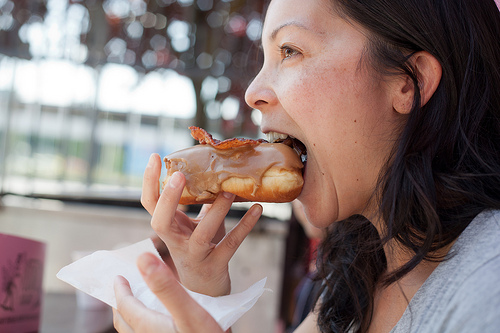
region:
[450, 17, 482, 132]
a person with black hair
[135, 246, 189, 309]
the thumb of a person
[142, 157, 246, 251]
the fingers of a person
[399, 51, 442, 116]
the left ear of a person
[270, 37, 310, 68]
the left eye of a person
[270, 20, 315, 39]
a person's eyebrow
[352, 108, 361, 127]
a mole on a person's skin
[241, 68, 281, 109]
a person's nose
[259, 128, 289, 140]
a person's teeth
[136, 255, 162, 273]
a person's fingernail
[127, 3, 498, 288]
The woman is holding a donut.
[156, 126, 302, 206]
The donut is brown.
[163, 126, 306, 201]
The donut has back on top.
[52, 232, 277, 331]
The woman is holding a napkin.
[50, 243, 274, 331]
The napkin is white in color.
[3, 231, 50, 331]
The object in the background is red and black.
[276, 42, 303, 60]
The woman's eye is brown.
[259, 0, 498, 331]
The woman's hair is brown.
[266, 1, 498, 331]
The woman's hair is long.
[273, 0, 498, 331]
The woman's shirt is gray.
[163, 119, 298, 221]
doughnut in woman's mouth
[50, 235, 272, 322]
napkin in woman's hand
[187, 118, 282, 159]
chip on a doughnut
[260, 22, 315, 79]
left eye on a woman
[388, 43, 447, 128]
left ear of a woman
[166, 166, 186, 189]
nail on a finger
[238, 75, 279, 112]
nose on a woman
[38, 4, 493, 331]
woman eating a doughnut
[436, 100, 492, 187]
black hair of a woman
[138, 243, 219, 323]
thumb of a woman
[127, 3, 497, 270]
woman eating a designer donut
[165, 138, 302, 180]
icing on a donut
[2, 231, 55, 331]
a purple sign on a window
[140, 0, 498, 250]
a woman biting a donut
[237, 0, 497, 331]
a woman with black hair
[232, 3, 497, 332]
a woman wearing a gray shirt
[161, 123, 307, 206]
an brown iced donut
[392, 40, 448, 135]
a woman's left ear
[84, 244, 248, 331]
a woman's hand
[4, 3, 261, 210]
lights in the distance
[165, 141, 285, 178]
chcoclate is on the hotdog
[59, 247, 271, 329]
paper is on the hand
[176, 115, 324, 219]
the hotdog looks tasty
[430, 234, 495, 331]
the shirt is grey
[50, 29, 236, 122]
the background is blured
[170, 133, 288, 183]
the choclate is brown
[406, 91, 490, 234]
the hair is long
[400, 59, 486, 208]
the hair is black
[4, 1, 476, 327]
the scene is outdoors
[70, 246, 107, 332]
the cup is on the table